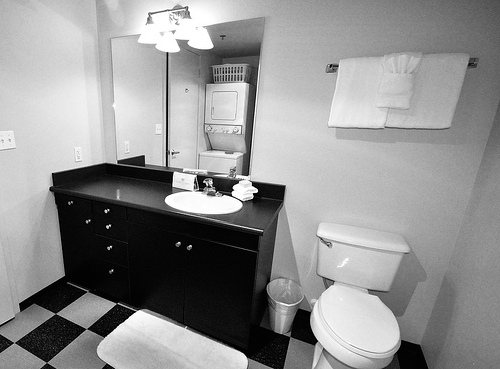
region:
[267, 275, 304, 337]
a small white trash can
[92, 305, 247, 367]
a white bath rug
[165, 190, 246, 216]
a white sink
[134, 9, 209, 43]
bathroom wall light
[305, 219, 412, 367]
a white toilet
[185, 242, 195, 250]
a gray cabinet handle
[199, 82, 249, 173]
a white stackable washer and dryer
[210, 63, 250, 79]
a white laundry basket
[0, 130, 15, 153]
a white wall switch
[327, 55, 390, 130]
a white bath towel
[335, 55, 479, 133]
towel hanging on a towel rack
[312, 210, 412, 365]
white toilet next to a wall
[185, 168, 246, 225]
white sink in a bathroom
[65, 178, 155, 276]
black vanity in a black vanity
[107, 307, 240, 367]
white carpet on bath room floor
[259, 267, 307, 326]
garbage can in next to toilet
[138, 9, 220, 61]
light fixture next to mirror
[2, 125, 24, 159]
light switch on a wall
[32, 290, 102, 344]
black and white floor tile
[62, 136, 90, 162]
light switch on a wall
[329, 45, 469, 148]
towels on a towel bar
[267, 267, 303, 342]
small trashcan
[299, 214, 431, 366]
ceramic toilet with lid closed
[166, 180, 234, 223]
ceramic bathroom sink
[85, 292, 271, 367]
bathroom floor mat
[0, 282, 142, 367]
checkered pattern on floor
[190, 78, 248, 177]
refection of a washer and dryer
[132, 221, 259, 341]
cabinet under the sink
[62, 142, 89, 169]
electrical outlet on the wall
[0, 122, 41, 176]
two light switches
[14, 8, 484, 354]
A bathroom scene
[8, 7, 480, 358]
The photo is in black and white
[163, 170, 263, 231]
A bathroom sink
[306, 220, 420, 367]
This is a commode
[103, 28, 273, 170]
A mirror is on the wall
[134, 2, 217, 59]
A light is above the mirror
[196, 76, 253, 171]
A washer and dryer is reflected in the mirror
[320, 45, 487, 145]
Towels are hanging on the towel rack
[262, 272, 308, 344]
A waste basket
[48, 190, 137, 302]
These are drawers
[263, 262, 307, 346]
small waste basket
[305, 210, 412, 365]
white toilet with silver handle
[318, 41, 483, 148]
white towels on a silver rack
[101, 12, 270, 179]
large square mirror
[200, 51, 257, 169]
stacked washer and dryer set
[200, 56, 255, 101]
plastic laundry basket on top of dryer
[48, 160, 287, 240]
black bathroom counter top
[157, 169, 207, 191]
paper triangle stand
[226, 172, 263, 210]
soap on top of wash cloths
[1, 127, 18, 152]
white light switch